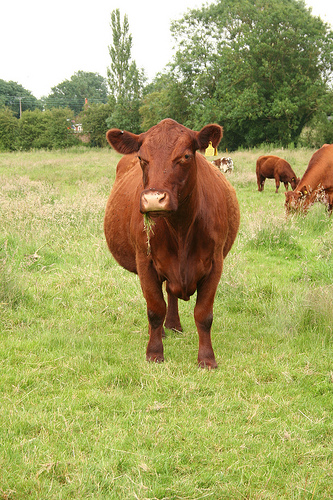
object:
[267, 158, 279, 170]
brown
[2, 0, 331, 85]
sky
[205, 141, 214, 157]
tag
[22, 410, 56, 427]
short yellow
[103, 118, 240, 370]
cattle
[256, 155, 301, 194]
cattle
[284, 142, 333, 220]
cattle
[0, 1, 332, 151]
trees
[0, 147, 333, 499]
field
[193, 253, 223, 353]
front leg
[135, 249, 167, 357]
front leg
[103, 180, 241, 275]
belly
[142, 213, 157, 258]
grass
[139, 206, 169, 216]
mouth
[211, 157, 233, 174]
cow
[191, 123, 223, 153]
ear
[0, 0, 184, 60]
clouds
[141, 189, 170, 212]
nose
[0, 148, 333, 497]
grass